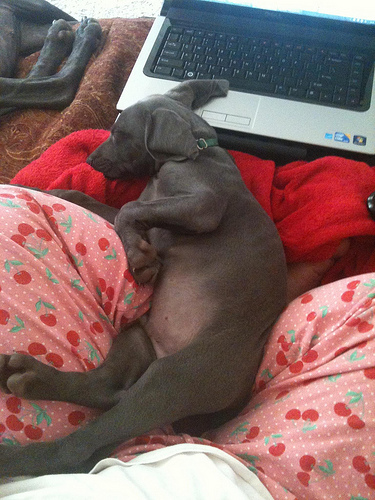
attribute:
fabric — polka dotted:
[0, 183, 374, 500]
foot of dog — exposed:
[0, 348, 34, 394]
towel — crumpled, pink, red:
[10, 127, 373, 288]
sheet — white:
[1, 443, 274, 500]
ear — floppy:
[167, 73, 233, 110]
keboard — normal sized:
[150, 21, 369, 112]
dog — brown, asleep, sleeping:
[1, 77, 291, 479]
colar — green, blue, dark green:
[189, 133, 218, 154]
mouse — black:
[365, 191, 374, 220]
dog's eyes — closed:
[107, 129, 121, 147]